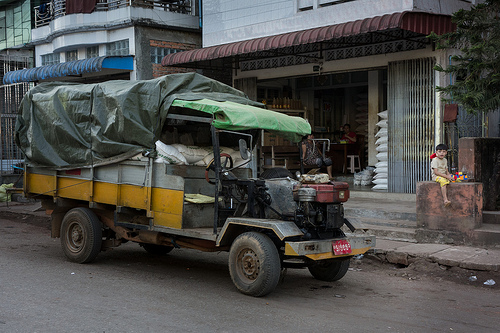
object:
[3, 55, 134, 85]
covering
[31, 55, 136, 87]
shop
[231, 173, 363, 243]
hood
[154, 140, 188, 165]
sack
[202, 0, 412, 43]
wall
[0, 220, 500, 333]
ground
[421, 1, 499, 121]
tree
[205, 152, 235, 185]
steering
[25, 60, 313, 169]
drapes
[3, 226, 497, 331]
road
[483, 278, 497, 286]
litter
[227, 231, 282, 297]
tire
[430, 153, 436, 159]
hairband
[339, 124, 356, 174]
woman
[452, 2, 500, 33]
leaves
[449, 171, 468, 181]
toy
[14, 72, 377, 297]
lorry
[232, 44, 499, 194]
shop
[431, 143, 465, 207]
boy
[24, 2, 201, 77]
buildings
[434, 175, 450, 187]
pants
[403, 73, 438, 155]
shutter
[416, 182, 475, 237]
wall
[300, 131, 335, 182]
women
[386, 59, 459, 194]
bonnet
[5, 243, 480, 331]
street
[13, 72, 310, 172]
canopy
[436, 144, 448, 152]
hair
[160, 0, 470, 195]
building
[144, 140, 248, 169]
goods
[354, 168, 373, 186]
bags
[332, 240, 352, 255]
number plate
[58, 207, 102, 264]
wheel